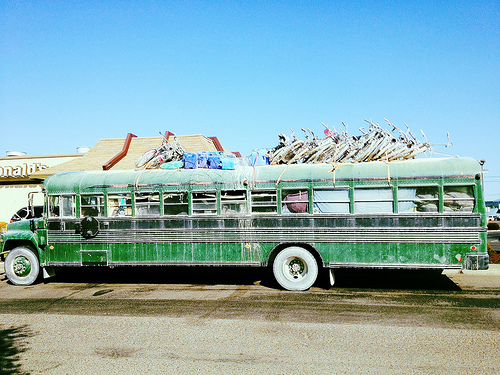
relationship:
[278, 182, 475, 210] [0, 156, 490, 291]
items in bus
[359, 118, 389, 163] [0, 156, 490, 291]
bicycle on bus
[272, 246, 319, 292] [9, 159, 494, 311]
snowboard of bus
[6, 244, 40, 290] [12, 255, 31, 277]
tire with green rim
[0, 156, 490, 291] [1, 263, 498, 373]
bus parked on road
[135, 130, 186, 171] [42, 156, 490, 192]
bicycles on roof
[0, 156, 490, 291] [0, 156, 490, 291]
bus on bus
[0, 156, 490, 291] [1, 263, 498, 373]
bus on road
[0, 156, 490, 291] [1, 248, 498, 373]
bus on street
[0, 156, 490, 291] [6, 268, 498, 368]
bus on street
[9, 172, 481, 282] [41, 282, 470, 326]
bus on street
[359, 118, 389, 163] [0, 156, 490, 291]
bicycle are on bus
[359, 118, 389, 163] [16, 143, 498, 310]
bicycle on bus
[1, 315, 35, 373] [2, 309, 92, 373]
shadow on ground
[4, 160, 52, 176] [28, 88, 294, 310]
letters are on building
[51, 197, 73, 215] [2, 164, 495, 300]
window on bus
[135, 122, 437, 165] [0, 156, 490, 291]
bicycles are on bus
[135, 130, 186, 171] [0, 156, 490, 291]
bicycles are on bus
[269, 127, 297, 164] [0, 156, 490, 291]
bicycle are on bus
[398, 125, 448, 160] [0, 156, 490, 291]
bicycles are on bus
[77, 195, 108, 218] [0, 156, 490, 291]
passenger window on bus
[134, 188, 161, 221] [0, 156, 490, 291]
passenger window on bus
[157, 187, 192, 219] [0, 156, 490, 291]
passenger window on bus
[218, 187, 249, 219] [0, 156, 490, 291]
passenger window on bus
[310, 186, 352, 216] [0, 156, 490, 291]
passenger window on bus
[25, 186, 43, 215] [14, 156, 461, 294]
side window on bus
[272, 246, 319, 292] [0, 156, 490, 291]
snowboard on bus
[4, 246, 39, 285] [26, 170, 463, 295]
tire on bus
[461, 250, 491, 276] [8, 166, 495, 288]
back bumper on bus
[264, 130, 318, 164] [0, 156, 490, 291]
bicycle on bus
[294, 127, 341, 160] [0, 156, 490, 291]
bicycle on bus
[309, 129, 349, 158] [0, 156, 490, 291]
bicycle on bus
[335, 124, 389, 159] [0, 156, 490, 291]
bicycle on bus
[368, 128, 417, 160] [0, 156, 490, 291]
bicycle on bus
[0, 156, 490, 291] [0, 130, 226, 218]
bus parked outside mcdonald's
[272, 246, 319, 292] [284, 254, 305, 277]
snowboard with center